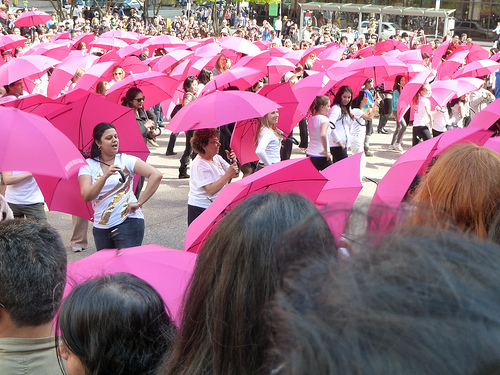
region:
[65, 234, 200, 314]
The umbrella is pink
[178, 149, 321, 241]
The umbrella is pink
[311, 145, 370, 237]
The umbrella is pink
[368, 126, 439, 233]
The umbrella is pink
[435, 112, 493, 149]
The umbrella is pink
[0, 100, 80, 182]
The umbrella is pink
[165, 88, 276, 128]
The umbrella is pink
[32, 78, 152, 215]
The umbrella is pink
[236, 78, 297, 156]
The umbrella is pink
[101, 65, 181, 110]
The umbrella is pink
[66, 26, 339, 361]
the woman are holding pink umbrellas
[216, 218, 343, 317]
the woman has dark hair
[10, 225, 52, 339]
the man has dark hair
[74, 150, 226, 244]
the woman is wearing a white shirt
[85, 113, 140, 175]
the woman has dark hair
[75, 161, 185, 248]
the woman has gold stripes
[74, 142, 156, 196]
the woman has a dark handle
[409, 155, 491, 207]
the woman has red hair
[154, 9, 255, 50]
the audience is watching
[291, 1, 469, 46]
the bus bench is in the background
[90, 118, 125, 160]
head of a person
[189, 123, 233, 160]
head of a person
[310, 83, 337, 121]
head of a person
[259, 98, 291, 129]
head of a person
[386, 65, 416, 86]
head of a person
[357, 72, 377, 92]
head of a person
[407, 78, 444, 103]
head of a person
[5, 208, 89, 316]
head of a person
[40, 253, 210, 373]
head of a person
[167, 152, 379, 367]
head of a person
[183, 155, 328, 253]
an open pink umbrella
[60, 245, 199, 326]
an open pink umbrella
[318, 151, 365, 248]
an open pink umbrella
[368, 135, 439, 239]
an open pink umbrella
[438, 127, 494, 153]
an open pink umbrella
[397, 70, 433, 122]
an open pink umbrella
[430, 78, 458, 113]
an open pink umbrella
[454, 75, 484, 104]
an open pink umbrella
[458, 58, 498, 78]
an open pink umbrella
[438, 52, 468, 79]
an open pink umbrella